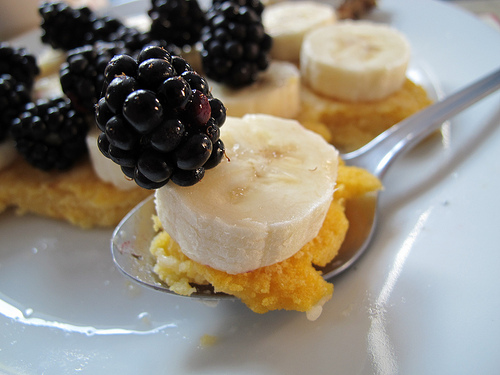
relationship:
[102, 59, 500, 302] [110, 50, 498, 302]
spoon with food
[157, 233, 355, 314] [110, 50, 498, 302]
fritter on spoon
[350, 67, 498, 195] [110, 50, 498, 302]
handle of spoon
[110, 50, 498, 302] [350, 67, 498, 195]
spoon has handle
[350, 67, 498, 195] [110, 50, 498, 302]
handle on spoon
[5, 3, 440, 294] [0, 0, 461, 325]
breakfast on breakfast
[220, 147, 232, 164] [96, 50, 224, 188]
stem on blackberry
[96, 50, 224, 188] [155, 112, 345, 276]
berries on bananna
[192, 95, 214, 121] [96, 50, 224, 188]
sement on blackberry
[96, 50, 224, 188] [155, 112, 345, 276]
blackberry on bananna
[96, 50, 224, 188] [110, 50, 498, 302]
blackberry on spoon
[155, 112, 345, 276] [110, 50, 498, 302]
bananna on spoon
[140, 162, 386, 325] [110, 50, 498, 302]
crust on spoon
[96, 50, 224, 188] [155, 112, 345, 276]
raspberry on bananna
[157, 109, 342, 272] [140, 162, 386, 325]
slice on pancake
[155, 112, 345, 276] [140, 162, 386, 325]
bananna on pancake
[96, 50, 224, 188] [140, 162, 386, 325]
raspberry on pancake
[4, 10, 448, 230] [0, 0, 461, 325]
pancake on breakfast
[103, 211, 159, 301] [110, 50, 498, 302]
tip of spoon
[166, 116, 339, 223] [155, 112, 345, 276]
top of bananna